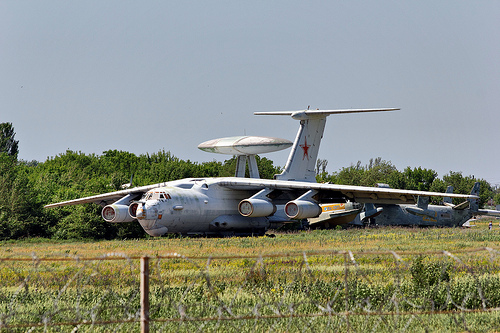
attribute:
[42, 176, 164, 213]
right side wing — large, right side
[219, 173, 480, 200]
left side wing — large, left side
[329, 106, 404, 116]
left wing — small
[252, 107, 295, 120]
right wing — small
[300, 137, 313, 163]
star — red, painted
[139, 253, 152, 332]
post — wooden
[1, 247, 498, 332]
fence — barb wire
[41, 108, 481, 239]
plane — large, grey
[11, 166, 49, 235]
tree — in the background, green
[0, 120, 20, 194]
tree — in the background, green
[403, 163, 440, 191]
tree — in the background, green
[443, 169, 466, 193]
tree — in the background, green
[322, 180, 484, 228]
plane — smaller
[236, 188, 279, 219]
engine — white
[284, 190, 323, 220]
engine — white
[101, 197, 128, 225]
engine — white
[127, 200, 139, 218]
engine — white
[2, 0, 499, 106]
sky — cloudless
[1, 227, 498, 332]
field — grassy, green